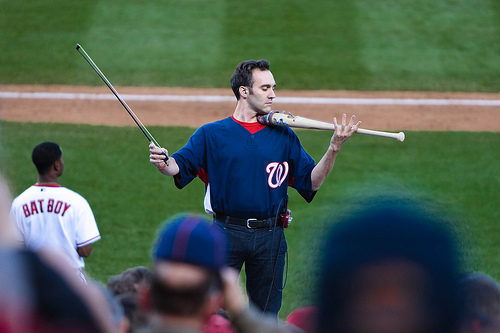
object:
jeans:
[210, 219, 288, 325]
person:
[310, 191, 472, 333]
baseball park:
[0, 0, 498, 319]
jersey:
[10, 184, 102, 271]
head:
[135, 259, 222, 322]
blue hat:
[152, 211, 231, 269]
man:
[132, 213, 309, 333]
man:
[146, 60, 360, 325]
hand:
[331, 114, 362, 144]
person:
[153, 50, 361, 222]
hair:
[230, 60, 270, 102]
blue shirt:
[170, 115, 318, 219]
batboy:
[22, 198, 71, 217]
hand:
[149, 144, 169, 165]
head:
[31, 141, 65, 178]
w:
[266, 161, 289, 188]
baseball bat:
[257, 111, 406, 143]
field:
[4, 0, 498, 320]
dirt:
[23, 79, 213, 129]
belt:
[213, 212, 287, 229]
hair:
[30, 141, 61, 175]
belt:
[212, 212, 283, 229]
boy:
[4, 140, 102, 287]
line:
[0, 89, 500, 106]